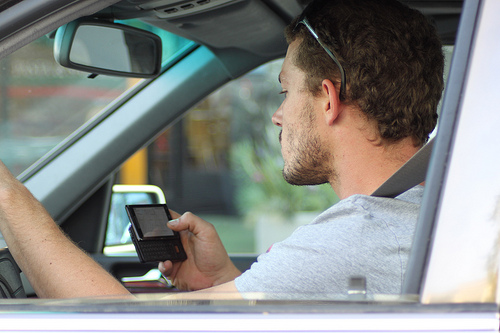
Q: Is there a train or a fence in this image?
A: No, there are no fences or trains.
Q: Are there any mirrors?
A: Yes, there is a mirror.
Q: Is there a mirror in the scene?
A: Yes, there is a mirror.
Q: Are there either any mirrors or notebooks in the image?
A: Yes, there is a mirror.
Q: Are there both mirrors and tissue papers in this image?
A: No, there is a mirror but no tissues.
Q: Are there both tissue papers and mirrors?
A: No, there is a mirror but no tissues.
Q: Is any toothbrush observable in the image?
A: No, there are no toothbrushes.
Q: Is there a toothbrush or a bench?
A: No, there are no toothbrushes or benches.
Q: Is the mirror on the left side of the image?
A: Yes, the mirror is on the left of the image.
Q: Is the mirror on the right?
A: No, the mirror is on the left of the image.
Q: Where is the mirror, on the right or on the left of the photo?
A: The mirror is on the left of the image.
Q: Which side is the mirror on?
A: The mirror is on the left of the image.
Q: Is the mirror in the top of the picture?
A: Yes, the mirror is in the top of the image.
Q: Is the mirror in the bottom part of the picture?
A: No, the mirror is in the top of the image.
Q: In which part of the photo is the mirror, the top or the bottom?
A: The mirror is in the top of the image.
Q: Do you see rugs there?
A: No, there are no rugs.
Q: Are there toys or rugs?
A: No, there are no rugs or toys.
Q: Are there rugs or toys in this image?
A: No, there are no rugs or toys.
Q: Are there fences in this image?
A: No, there are no fences.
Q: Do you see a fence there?
A: No, there are no fences.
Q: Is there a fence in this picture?
A: No, there are no fences.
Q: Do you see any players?
A: No, there are no players.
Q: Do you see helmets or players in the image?
A: No, there are no players or helmets.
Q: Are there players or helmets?
A: No, there are no players or helmets.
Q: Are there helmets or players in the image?
A: No, there are no players or helmets.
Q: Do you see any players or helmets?
A: No, there are no players or helmets.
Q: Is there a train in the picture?
A: No, there are no trains.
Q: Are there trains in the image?
A: No, there are no trains.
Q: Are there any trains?
A: No, there are no trains.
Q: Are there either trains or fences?
A: No, there are no trains or fences.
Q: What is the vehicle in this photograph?
A: The vehicle is a car.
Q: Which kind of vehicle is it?
A: The vehicle is a car.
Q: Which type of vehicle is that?
A: That is a car.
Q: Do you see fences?
A: No, there are no fences.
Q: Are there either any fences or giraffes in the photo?
A: No, there are no fences or giraffes.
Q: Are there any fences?
A: No, there are no fences.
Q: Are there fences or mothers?
A: No, there are no fences or mothers.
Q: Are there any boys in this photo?
A: No, there are no boys.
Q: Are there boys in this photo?
A: No, there are no boys.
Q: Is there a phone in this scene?
A: Yes, there is a phone.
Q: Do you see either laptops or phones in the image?
A: Yes, there is a phone.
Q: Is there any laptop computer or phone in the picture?
A: Yes, there is a phone.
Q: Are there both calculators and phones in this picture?
A: No, there is a phone but no calculators.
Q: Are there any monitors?
A: No, there are no monitors.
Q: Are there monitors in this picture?
A: No, there are no monitors.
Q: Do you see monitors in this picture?
A: No, there are no monitors.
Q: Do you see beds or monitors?
A: No, there are no monitors or beds.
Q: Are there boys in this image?
A: No, there are no boys.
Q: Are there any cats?
A: No, there are no cats.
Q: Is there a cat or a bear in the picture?
A: No, there are no cats or bears.